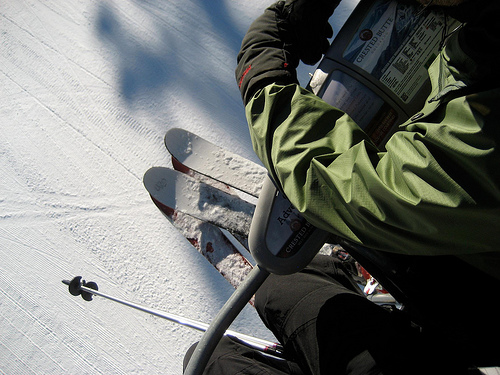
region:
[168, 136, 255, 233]
white ski with bits of snow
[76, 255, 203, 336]
skier's ski pole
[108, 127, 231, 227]
tips of a skier's skis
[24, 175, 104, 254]
snow on the ground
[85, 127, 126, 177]
ruts in the snow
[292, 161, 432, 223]
wrinkles of the jacket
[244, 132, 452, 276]
arm of the skier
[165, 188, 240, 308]
shadow on the skis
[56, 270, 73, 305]
tip of the ski pole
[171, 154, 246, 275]
snow on the ski tops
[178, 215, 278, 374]
bar of the ski lift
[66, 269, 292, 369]
The ski pole on the left of the person.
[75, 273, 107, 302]
The two silver cylinders at the bottom of the ski pole.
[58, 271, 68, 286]
The spiky tip at the end of the ski pole.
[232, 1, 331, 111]
The black glove on the person's hand.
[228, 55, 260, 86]
The red writing on the person's glove.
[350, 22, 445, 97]
The white sticker on the snow lift.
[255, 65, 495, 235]
The left sleeve of the person's jacket.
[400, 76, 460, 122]
The two black buttons on the shoulder area of the jacket.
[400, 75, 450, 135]
The strap where the two black buttons are.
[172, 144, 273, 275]
The snow on the skis.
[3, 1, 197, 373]
White snow on ground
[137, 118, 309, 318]
Skis with snow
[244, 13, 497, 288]
jacket is green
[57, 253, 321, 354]
Ski pole over snow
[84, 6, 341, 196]
Shadow on snow covered ground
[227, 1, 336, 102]
Black glove with red logo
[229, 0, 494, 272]
person wearing green jacket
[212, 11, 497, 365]
person on snow mobile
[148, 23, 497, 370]
Person wearing skis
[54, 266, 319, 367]
Ski pole is silver with black tip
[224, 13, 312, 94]
black gloves with red mark